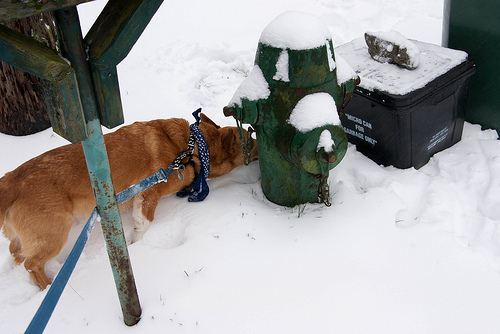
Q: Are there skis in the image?
A: No, there are no skis.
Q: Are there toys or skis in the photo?
A: No, there are no skis or toys.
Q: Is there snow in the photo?
A: Yes, there is snow.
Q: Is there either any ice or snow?
A: Yes, there is snow.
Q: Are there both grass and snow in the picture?
A: No, there is snow but no grass.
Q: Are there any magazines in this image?
A: No, there are no magazines.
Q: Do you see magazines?
A: No, there are no magazines.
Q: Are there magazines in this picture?
A: No, there are no magazines.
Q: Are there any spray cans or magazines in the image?
A: No, there are no magazines or spray cans.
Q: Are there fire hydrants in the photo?
A: Yes, there is a fire hydrant.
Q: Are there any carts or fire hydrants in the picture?
A: Yes, there is a fire hydrant.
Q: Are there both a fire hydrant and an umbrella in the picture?
A: No, there is a fire hydrant but no umbrellas.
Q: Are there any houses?
A: No, there are no houses.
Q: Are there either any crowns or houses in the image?
A: No, there are no houses or crowns.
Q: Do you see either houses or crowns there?
A: No, there are no houses or crowns.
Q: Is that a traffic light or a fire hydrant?
A: That is a fire hydrant.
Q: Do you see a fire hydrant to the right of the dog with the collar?
A: Yes, there is a fire hydrant to the right of the dog.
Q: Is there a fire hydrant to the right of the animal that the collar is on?
A: Yes, there is a fire hydrant to the right of the dog.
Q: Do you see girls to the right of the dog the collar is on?
A: No, there is a fire hydrant to the right of the dog.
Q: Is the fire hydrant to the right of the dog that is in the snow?
A: Yes, the fire hydrant is to the right of the dog.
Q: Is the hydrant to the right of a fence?
A: No, the hydrant is to the right of the dog.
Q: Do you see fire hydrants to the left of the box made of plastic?
A: Yes, there is a fire hydrant to the left of the box.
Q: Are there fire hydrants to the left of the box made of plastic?
A: Yes, there is a fire hydrant to the left of the box.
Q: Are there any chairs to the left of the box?
A: No, there is a fire hydrant to the left of the box.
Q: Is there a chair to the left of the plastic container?
A: No, there is a fire hydrant to the left of the box.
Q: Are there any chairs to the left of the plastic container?
A: No, there is a fire hydrant to the left of the box.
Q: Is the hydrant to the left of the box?
A: Yes, the hydrant is to the left of the box.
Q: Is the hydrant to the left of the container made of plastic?
A: Yes, the hydrant is to the left of the box.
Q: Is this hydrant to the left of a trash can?
A: No, the hydrant is to the left of the box.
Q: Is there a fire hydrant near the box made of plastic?
A: Yes, there is a fire hydrant near the box.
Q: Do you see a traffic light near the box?
A: No, there is a fire hydrant near the box.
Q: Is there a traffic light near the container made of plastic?
A: No, there is a fire hydrant near the box.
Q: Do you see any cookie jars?
A: No, there are no cookie jars.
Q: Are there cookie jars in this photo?
A: No, there are no cookie jars.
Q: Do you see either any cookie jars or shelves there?
A: No, there are no cookie jars or shelves.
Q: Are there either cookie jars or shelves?
A: No, there are no cookie jars or shelves.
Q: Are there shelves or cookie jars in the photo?
A: No, there are no cookie jars or shelves.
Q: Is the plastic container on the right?
A: Yes, the box is on the right of the image.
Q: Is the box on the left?
A: No, the box is on the right of the image.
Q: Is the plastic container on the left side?
A: No, the box is on the right of the image.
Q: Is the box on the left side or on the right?
A: The box is on the right of the image.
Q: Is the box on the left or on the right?
A: The box is on the right of the image.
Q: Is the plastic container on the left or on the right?
A: The box is on the right of the image.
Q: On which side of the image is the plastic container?
A: The box is on the right of the image.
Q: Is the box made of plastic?
A: Yes, the box is made of plastic.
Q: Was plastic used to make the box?
A: Yes, the box is made of plastic.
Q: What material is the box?
A: The box is made of plastic.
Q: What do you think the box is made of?
A: The box is made of plastic.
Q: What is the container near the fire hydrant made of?
A: The box is made of plastic.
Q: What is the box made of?
A: The box is made of plastic.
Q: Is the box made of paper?
A: No, the box is made of plastic.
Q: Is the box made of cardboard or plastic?
A: The box is made of plastic.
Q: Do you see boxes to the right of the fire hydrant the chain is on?
A: Yes, there is a box to the right of the fire hydrant.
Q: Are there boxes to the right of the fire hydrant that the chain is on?
A: Yes, there is a box to the right of the fire hydrant.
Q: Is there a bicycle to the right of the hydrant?
A: No, there is a box to the right of the hydrant.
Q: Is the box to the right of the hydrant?
A: Yes, the box is to the right of the hydrant.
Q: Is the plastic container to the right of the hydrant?
A: Yes, the box is to the right of the hydrant.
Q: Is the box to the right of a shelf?
A: No, the box is to the right of the hydrant.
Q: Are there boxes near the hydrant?
A: Yes, there is a box near the hydrant.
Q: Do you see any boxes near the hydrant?
A: Yes, there is a box near the hydrant.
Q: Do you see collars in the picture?
A: Yes, there is a collar.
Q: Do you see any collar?
A: Yes, there is a collar.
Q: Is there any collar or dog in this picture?
A: Yes, there is a collar.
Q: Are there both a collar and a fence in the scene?
A: No, there is a collar but no fences.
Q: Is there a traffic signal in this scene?
A: No, there are no traffic lights.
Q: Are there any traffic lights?
A: No, there are no traffic lights.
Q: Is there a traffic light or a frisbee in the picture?
A: No, there are no traffic lights or frisbees.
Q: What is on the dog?
A: The collar is on the dog.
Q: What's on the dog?
A: The collar is on the dog.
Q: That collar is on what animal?
A: The collar is on the dog.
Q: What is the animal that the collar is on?
A: The animal is a dog.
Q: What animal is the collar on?
A: The collar is on the dog.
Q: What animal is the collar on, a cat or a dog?
A: The collar is on a dog.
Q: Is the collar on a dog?
A: Yes, the collar is on a dog.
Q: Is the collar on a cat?
A: No, the collar is on a dog.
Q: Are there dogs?
A: Yes, there is a dog.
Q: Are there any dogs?
A: Yes, there is a dog.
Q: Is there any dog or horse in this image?
A: Yes, there is a dog.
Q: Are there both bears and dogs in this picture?
A: No, there is a dog but no bears.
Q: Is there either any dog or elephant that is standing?
A: Yes, the dog is standing.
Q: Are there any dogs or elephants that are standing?
A: Yes, the dog is standing.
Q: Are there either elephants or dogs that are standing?
A: Yes, the dog is standing.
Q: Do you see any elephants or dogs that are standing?
A: Yes, the dog is standing.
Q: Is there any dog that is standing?
A: Yes, there is a dog that is standing.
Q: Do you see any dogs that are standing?
A: Yes, there is a dog that is standing.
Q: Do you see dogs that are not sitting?
A: Yes, there is a dog that is standing .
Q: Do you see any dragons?
A: No, there are no dragons.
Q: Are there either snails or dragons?
A: No, there are no dragons or snails.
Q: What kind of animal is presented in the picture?
A: The animal is a dog.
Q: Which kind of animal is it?
A: The animal is a dog.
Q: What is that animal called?
A: This is a dog.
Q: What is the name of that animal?
A: This is a dog.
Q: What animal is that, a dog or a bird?
A: This is a dog.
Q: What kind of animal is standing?
A: The animal is a dog.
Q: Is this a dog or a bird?
A: This is a dog.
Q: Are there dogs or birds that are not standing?
A: No, there is a dog but it is standing.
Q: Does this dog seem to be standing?
A: Yes, the dog is standing.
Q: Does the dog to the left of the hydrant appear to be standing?
A: Yes, the dog is standing.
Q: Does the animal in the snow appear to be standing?
A: Yes, the dog is standing.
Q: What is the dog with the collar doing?
A: The dog is standing.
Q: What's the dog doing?
A: The dog is standing.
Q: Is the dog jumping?
A: No, the dog is standing.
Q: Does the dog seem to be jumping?
A: No, the dog is standing.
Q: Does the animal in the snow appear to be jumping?
A: No, the dog is standing.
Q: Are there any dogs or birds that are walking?
A: No, there is a dog but it is standing.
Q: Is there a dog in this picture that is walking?
A: No, there is a dog but it is standing.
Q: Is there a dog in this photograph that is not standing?
A: No, there is a dog but it is standing.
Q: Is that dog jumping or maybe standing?
A: The dog is standing.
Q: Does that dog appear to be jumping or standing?
A: The dog is standing.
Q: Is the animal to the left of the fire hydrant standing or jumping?
A: The dog is standing.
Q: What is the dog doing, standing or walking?
A: The dog is standing.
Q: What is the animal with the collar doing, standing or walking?
A: The dog is standing.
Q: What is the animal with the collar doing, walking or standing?
A: The dog is standing.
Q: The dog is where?
A: The dog is in the snow.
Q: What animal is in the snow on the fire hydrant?
A: The dog is in the snow.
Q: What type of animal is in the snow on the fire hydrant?
A: The animal is a dog.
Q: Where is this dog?
A: The dog is in the snow.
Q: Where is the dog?
A: The dog is in the snow.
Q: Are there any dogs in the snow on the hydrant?
A: Yes, there is a dog in the snow.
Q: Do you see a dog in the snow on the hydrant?
A: Yes, there is a dog in the snow.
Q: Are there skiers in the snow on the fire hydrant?
A: No, there is a dog in the snow.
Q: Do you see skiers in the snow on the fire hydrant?
A: No, there is a dog in the snow.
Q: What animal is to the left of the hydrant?
A: The animal is a dog.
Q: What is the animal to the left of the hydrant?
A: The animal is a dog.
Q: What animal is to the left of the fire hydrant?
A: The animal is a dog.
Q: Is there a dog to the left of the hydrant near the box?
A: Yes, there is a dog to the left of the hydrant.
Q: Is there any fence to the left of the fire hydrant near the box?
A: No, there is a dog to the left of the hydrant.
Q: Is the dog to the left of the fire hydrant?
A: Yes, the dog is to the left of the fire hydrant.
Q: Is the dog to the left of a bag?
A: No, the dog is to the left of the fire hydrant.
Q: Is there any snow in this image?
A: Yes, there is snow.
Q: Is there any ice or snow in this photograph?
A: Yes, there is snow.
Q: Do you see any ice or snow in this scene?
A: Yes, there is snow.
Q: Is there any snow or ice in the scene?
A: Yes, there is snow.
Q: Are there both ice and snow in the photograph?
A: No, there is snow but no ice.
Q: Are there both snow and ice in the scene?
A: No, there is snow but no ice.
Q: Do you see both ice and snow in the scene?
A: No, there is snow but no ice.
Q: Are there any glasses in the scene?
A: No, there are no glasses.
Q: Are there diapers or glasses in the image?
A: No, there are no glasses or diapers.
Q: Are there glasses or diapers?
A: No, there are no glasses or diapers.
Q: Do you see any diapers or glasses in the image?
A: No, there are no glasses or diapers.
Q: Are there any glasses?
A: No, there are no glasses.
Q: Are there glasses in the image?
A: No, there are no glasses.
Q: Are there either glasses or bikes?
A: No, there are no glasses or bikes.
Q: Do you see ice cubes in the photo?
A: No, there are no ice cubes.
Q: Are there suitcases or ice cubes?
A: No, there are no ice cubes or suitcases.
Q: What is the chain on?
A: The chain is on the fire hydrant.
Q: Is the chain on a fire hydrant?
A: Yes, the chain is on a fire hydrant.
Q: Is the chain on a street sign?
A: No, the chain is on a fire hydrant.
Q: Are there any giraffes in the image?
A: No, there are no giraffes.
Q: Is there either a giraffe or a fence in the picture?
A: No, there are no giraffes or fences.